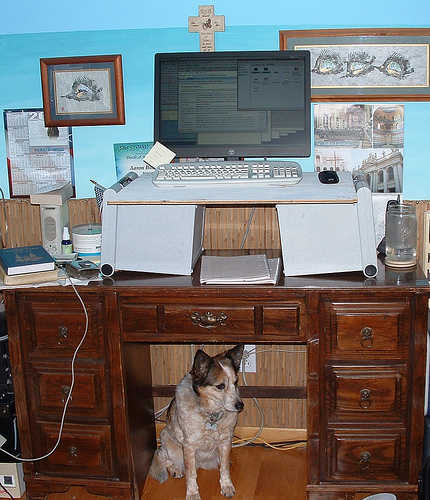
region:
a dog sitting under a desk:
[147, 342, 247, 498]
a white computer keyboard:
[155, 161, 302, 184]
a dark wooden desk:
[5, 246, 424, 493]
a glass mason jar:
[385, 199, 415, 261]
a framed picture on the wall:
[39, 56, 124, 126]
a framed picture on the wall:
[276, 29, 428, 99]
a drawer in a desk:
[324, 299, 406, 360]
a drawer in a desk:
[325, 364, 405, 419]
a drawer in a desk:
[325, 422, 407, 480]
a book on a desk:
[4, 245, 51, 270]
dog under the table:
[118, 348, 265, 469]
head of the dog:
[188, 339, 251, 414]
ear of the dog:
[185, 344, 214, 375]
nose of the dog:
[226, 391, 242, 414]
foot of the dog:
[172, 457, 204, 492]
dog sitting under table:
[172, 347, 258, 457]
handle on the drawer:
[343, 381, 381, 417]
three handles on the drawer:
[330, 322, 382, 477]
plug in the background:
[238, 341, 265, 377]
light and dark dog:
[172, 347, 244, 440]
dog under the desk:
[137, 344, 269, 468]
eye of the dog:
[212, 377, 231, 398]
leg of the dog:
[164, 457, 203, 496]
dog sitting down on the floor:
[153, 343, 259, 465]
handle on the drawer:
[182, 301, 234, 350]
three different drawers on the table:
[317, 301, 410, 471]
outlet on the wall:
[241, 344, 263, 376]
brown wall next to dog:
[267, 357, 293, 382]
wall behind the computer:
[24, 4, 68, 33]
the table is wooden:
[22, 293, 421, 490]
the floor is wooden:
[251, 449, 304, 498]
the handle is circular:
[354, 453, 386, 476]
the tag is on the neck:
[201, 401, 229, 427]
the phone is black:
[316, 164, 351, 182]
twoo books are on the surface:
[211, 245, 283, 291]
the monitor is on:
[160, 57, 316, 161]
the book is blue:
[11, 242, 62, 269]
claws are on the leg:
[223, 478, 245, 498]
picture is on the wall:
[281, 25, 429, 103]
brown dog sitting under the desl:
[152, 345, 244, 498]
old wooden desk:
[6, 250, 425, 498]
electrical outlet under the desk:
[238, 345, 255, 372]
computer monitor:
[154, 51, 313, 156]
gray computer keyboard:
[155, 164, 300, 184]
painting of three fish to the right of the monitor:
[286, 34, 429, 97]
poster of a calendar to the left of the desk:
[4, 108, 73, 195]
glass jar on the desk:
[385, 204, 413, 262]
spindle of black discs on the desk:
[73, 223, 101, 254]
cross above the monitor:
[188, 5, 226, 49]